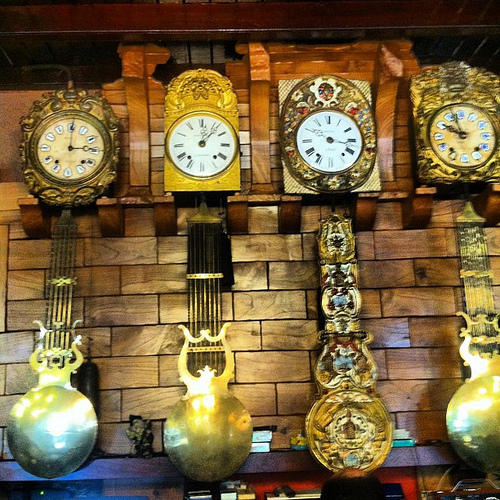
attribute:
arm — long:
[203, 129, 215, 139]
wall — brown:
[240, 324, 306, 392]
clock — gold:
[161, 62, 258, 487]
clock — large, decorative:
[276, 74, 403, 475]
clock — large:
[6, 79, 123, 477]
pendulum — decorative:
[6, 208, 110, 477]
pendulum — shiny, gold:
[162, 321, 254, 481]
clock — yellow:
[158, 78, 250, 205]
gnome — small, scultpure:
[127, 405, 157, 463]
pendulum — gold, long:
[170, 201, 240, 476]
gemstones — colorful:
[309, 80, 336, 114]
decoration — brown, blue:
[317, 275, 370, 327]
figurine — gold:
[129, 420, 154, 464]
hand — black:
[64, 114, 77, 150]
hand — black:
[65, 142, 92, 153]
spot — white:
[185, 370, 218, 416]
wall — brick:
[3, 2, 499, 458]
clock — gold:
[164, 65, 248, 195]